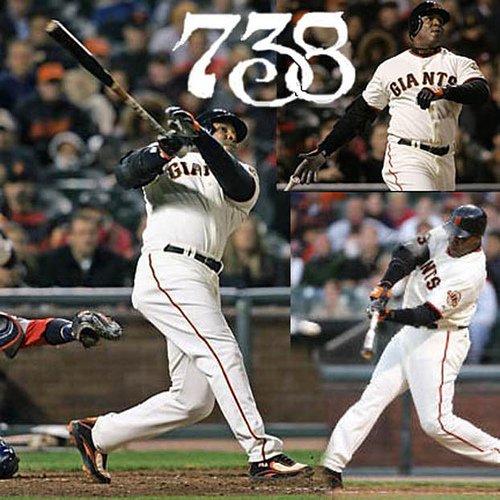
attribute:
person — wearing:
[37, 25, 314, 490]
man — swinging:
[64, 107, 309, 485]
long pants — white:
[90, 240, 285, 462]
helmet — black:
[437, 204, 486, 239]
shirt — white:
[362, 50, 490, 143]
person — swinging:
[310, 203, 498, 488]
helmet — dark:
[433, 205, 490, 242]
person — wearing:
[346, 200, 485, 460]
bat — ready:
[361, 297, 385, 368]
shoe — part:
[246, 450, 314, 482]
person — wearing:
[0, 308, 73, 478]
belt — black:
[151, 243, 229, 275]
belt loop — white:
[179, 240, 190, 259]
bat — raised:
[40, 17, 175, 151]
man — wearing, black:
[294, 3, 489, 188]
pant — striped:
[67, 245, 314, 487]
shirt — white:
[137, 149, 260, 263]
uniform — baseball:
[92, 146, 284, 460]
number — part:
[226, 9, 316, 115]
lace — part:
[274, 451, 296, 467]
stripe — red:
[436, 331, 496, 458]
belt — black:
[164, 247, 223, 272]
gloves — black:
[153, 108, 202, 155]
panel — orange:
[370, 285, 393, 300]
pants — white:
[88, 250, 285, 463]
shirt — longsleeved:
[320, 82, 490, 174]